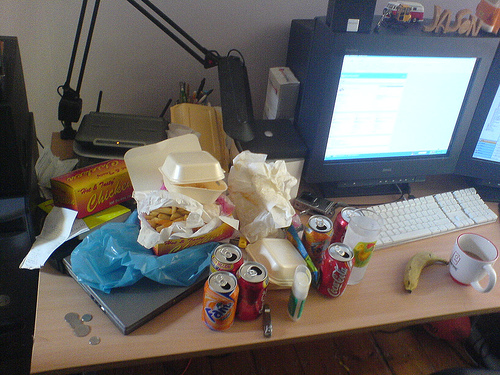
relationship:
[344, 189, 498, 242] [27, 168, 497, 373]
keyboard on desk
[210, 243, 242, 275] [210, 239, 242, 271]
can of soda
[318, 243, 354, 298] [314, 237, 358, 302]
can of soda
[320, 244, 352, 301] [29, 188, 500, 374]
coke soda on desk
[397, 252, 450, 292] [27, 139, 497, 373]
banana on desk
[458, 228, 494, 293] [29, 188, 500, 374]
coffee on desk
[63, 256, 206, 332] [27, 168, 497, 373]
laptop on desk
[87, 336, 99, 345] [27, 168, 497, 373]
coins on desk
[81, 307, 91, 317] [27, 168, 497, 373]
coins on desk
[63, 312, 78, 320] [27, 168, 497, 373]
coins on desk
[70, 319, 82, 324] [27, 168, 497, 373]
coins on desk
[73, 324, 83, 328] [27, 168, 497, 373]
coins on desk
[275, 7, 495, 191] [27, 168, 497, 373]
monitor on desk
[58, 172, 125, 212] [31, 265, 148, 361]
box on desk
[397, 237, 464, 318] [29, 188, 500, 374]
banana on desk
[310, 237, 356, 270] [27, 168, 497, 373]
open coke on desk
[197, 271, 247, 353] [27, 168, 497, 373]
can on desk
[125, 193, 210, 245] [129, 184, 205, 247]
fries in paper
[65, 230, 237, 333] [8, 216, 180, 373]
laptop on desk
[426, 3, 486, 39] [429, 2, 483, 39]
name in wood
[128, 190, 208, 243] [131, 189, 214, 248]
french fries on paper